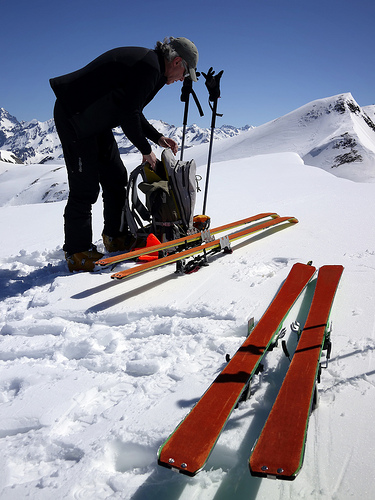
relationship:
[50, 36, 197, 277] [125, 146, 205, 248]
man looking in backpack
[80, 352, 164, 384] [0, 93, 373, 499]
footprint made in snow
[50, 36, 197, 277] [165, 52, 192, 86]
man has face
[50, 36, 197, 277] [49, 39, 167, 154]
man wearing jacket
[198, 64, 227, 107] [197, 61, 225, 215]
glove hanging on pole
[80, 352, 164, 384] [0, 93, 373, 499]
footprint inside of snow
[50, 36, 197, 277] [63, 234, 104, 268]
man wearing boot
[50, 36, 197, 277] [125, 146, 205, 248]
man looking through backpack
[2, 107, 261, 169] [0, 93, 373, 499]
mountain has snow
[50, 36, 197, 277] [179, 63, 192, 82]
man with sunglasses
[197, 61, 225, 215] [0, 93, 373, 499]
pole stuck i snow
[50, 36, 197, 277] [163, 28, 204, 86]
man wearing hat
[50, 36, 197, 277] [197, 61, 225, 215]
man has pole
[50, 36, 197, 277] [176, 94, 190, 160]
man has pole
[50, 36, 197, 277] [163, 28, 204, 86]
man has hat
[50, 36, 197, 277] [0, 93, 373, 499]
man standing in snow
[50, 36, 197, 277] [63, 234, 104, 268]
man has boot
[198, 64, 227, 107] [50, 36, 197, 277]
glove of man